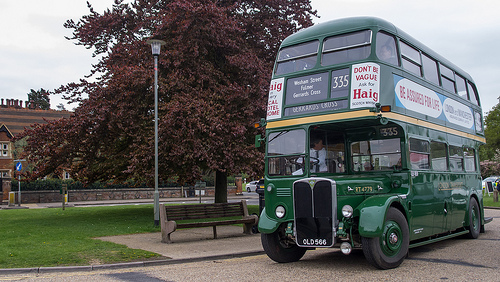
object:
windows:
[273, 30, 398, 76]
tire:
[360, 204, 411, 270]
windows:
[319, 30, 371, 67]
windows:
[397, 37, 422, 76]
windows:
[419, 52, 441, 86]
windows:
[440, 61, 457, 92]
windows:
[453, 72, 465, 98]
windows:
[266, 128, 307, 174]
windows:
[303, 131, 350, 177]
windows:
[347, 132, 401, 172]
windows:
[403, 134, 432, 170]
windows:
[428, 140, 448, 172]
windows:
[463, 144, 475, 174]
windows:
[445, 139, 464, 171]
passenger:
[377, 33, 399, 66]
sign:
[349, 62, 380, 111]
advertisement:
[346, 61, 381, 110]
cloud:
[8, 9, 62, 84]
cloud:
[454, 22, 497, 57]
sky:
[0, 5, 135, 115]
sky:
[310, 2, 499, 123]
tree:
[11, 0, 322, 204]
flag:
[12, 160, 25, 173]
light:
[267, 184, 275, 191]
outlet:
[257, 19, 488, 268]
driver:
[306, 136, 330, 171]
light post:
[149, 38, 166, 219]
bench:
[159, 199, 260, 242]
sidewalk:
[92, 222, 266, 259]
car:
[252, 15, 494, 271]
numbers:
[330, 74, 350, 88]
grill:
[289, 174, 341, 248]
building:
[0, 104, 76, 183]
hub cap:
[381, 220, 401, 256]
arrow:
[14, 163, 22, 170]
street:
[3, 209, 499, 281]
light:
[342, 205, 354, 218]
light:
[275, 204, 288, 216]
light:
[338, 241, 352, 254]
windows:
[265, 127, 308, 157]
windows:
[465, 78, 481, 106]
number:
[331, 74, 351, 88]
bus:
[254, 15, 485, 271]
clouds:
[0, 0, 499, 112]